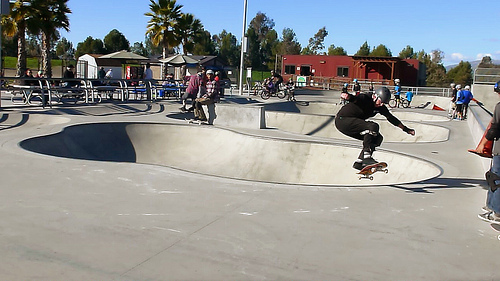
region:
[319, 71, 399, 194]
Person on a skateboard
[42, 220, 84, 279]
PArt of concrete pavement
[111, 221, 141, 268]
PArt of concrete pavement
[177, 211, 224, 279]
PArt of concrete pavement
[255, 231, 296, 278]
PArt of concrete pavement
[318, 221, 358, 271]
PArt of concrete pavement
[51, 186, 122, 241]
PArt of concrete pavement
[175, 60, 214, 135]
People on the pavement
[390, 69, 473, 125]
People on the pavement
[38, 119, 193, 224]
PArt of concrete pavement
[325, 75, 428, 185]
skater wears black clothes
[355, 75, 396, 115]
a gray helmet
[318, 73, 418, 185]
arms of skater are extended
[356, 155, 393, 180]
a brown skateboard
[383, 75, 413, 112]
person on a bike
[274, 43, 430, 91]
a red building in front the trees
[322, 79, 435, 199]
skater on border of skating trail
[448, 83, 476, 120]
people wearing blue shirt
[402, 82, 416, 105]
a little boy wearing blue top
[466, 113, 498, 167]
an orange cone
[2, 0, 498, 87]
trees behind the skatepark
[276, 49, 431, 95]
red building with porch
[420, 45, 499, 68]
white and grey clouds in the distance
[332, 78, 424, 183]
skapteboarder doing a jump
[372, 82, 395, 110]
grey helmet on head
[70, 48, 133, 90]
small storage building with brown roof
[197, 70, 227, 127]
skateboarder with plaid shirt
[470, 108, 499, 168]
orange cone on concrete surface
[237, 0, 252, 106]
silver utility pole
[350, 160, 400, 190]
skateboard with red bottom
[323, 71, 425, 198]
skateboarder in a park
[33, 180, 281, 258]
flat ground of a skatepark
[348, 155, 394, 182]
skateboard on top of ramp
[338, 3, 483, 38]
blue sky in the distance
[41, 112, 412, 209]
ramp in a skate park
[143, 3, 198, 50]
palm tree behind park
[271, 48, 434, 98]
building by the park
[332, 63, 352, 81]
window on a building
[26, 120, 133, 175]
shadow in the ditch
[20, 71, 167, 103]
benches in the park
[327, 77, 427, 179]
a guy wearing a protective head gear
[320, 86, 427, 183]
a skateboarder doing a jump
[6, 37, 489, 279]
a skateboard play ground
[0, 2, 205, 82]
a lot of tall trees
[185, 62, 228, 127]
skateboarder wearing a stripped shirt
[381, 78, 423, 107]
kid on a bicycle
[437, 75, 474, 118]
bunch of skateboarders on the side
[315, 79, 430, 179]
guy is wearing a black shirt and jeans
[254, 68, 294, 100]
guy is riding a bicycle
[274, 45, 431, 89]
a red facility building